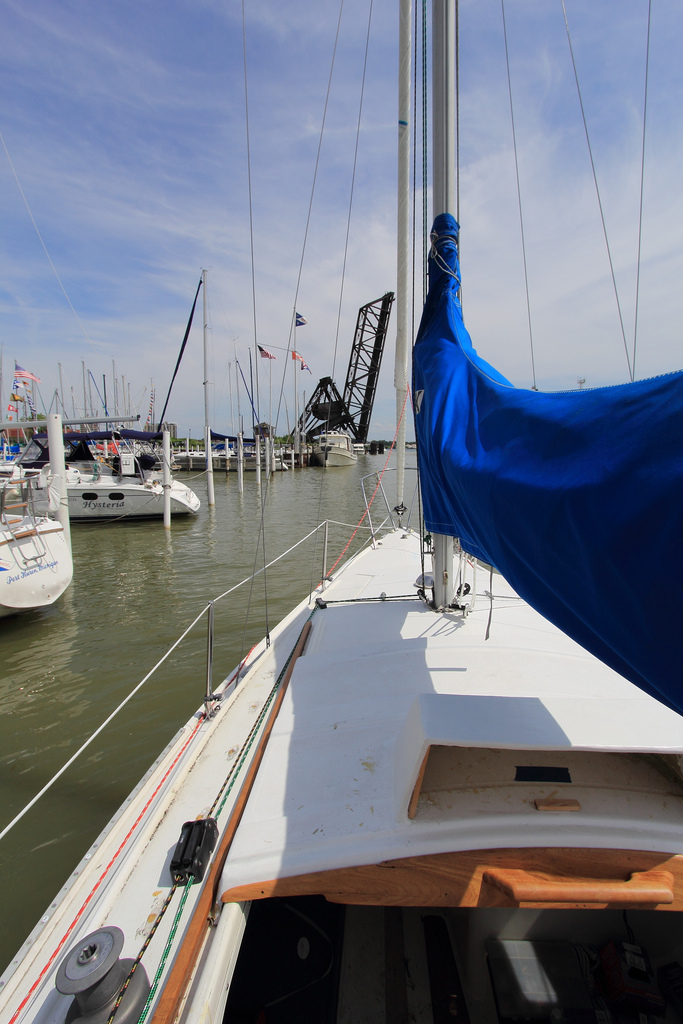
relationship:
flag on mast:
[250, 342, 277, 368] [227, 298, 318, 428]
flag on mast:
[293, 310, 310, 328] [227, 298, 318, 428]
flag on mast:
[286, 347, 304, 364] [227, 298, 318, 428]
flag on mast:
[300, 357, 312, 378] [227, 298, 318, 428]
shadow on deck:
[267, 593, 448, 789] [15, 531, 672, 1020]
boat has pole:
[3, 3, 661, 1021] [201, 603, 214, 712]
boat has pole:
[3, 3, 661, 1021] [261, 566, 269, 633]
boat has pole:
[3, 3, 661, 1021] [432, 533, 455, 616]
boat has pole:
[3, 3, 661, 1021] [387, 4, 408, 526]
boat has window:
[39, 457, 201, 524] [80, 488, 99, 504]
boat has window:
[32, 470, 200, 524] [103, 489, 122, 503]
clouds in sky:
[6, 6, 660, 441] [7, 3, 661, 442]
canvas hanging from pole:
[407, 212, 661, 709] [428, 2, 464, 610]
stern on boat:
[0, 521, 75, 609] [0, 511, 74, 609]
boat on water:
[309, 424, 381, 472] [237, 469, 388, 522]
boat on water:
[3, 3, 661, 1021] [2, 453, 424, 982]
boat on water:
[39, 457, 201, 524] [2, 453, 424, 982]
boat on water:
[168, 435, 287, 484] [2, 453, 424, 982]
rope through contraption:
[100, 628, 299, 1020] [161, 815, 220, 888]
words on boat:
[76, 496, 131, 513] [39, 457, 201, 524]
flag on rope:
[293, 307, 310, 335] [287, 315, 301, 442]